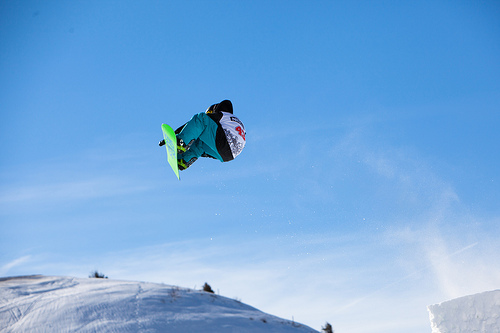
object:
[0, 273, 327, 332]
snow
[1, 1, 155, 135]
sky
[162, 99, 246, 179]
snowboarder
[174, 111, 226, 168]
pants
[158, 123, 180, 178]
snowboard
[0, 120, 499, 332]
clouds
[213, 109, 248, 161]
jacket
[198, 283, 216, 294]
tree